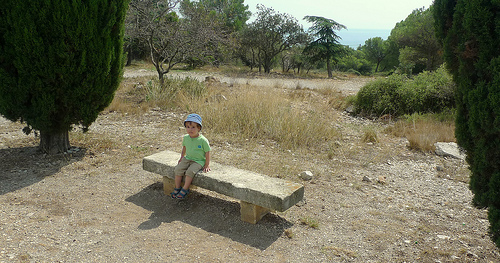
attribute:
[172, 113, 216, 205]
person — young, little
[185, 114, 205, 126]
hat — blue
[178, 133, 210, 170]
shirt — green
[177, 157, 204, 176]
short — tan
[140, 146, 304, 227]
park bench — tan, wooden, off white, stone, long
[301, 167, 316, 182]
rock — white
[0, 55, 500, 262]
ground — brown, dirt, rocky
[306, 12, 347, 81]
tree — leafy, green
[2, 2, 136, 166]
shrub — large, green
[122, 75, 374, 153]
weeds — brown, dry, dead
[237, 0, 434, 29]
sky — white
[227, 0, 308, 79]
tree — green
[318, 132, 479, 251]
gravel — gray